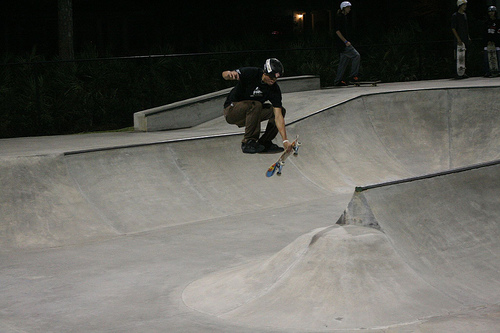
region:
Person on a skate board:
[199, 59, 319, 178]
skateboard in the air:
[267, 130, 312, 173]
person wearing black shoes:
[233, 138, 285, 160]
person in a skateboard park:
[324, 4, 386, 93]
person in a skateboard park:
[442, 4, 472, 79]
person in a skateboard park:
[483, 5, 495, 87]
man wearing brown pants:
[218, 101, 279, 135]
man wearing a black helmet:
[261, 57, 280, 94]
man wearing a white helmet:
[336, 2, 352, 8]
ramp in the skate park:
[340, 148, 499, 314]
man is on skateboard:
[212, 58, 314, 178]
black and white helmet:
[264, 59, 288, 95]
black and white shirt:
[218, 82, 277, 111]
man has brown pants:
[227, 93, 282, 130]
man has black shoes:
[233, 126, 279, 167]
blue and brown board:
[260, 122, 306, 182]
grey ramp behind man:
[134, 67, 295, 142]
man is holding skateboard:
[247, 92, 311, 181]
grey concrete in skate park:
[37, 167, 293, 301]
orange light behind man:
[287, 6, 318, 31]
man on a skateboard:
[203, 49, 326, 191]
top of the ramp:
[332, 163, 481, 290]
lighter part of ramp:
[232, 267, 319, 315]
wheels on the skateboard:
[267, 160, 297, 180]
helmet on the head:
[260, 53, 282, 75]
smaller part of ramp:
[126, 95, 201, 129]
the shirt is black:
[267, 89, 278, 99]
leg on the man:
[270, 110, 290, 140]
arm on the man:
[219, 70, 238, 77]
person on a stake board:
[203, 50, 314, 177]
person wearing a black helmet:
[261, 55, 306, 96]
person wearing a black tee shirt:
[218, 58, 285, 110]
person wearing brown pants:
[217, 88, 284, 138]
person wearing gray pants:
[332, 38, 366, 90]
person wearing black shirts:
[330, 12, 354, 56]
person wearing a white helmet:
[336, 0, 349, 12]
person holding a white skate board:
[447, 33, 482, 87]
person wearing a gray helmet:
[486, 1, 498, 13]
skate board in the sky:
[248, 134, 320, 189]